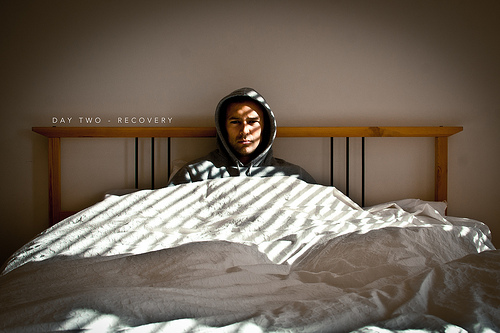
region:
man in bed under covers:
[175, 86, 317, 199]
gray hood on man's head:
[205, 84, 277, 164]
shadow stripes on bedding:
[188, 192, 303, 234]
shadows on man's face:
[237, 104, 267, 146]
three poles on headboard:
[320, 130, 375, 192]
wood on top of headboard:
[381, 119, 447, 142]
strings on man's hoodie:
[229, 159, 263, 178]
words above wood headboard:
[40, 111, 175, 129]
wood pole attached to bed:
[422, 146, 454, 211]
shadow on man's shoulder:
[195, 150, 231, 174]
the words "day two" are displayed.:
[49, 112, 102, 126]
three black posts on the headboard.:
[325, 131, 370, 207]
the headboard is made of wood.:
[33, 120, 465, 141]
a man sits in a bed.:
[212, 85, 277, 175]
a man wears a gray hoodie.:
[179, 88, 305, 188]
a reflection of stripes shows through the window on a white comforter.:
[152, 183, 337, 235]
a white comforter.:
[57, 255, 298, 320]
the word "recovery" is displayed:
[116, 115, 174, 127]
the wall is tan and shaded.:
[32, 5, 474, 87]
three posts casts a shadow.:
[118, 130, 175, 196]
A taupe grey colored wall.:
[1, 0, 496, 81]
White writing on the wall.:
[38, 112, 180, 125]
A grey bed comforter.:
[8, 265, 498, 305]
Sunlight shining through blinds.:
[116, 185, 329, 232]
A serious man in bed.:
[161, 87, 323, 183]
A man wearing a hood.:
[213, 86, 277, 168]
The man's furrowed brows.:
[223, 113, 266, 128]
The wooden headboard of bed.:
[28, 125, 215, 140]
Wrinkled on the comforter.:
[310, 260, 437, 310]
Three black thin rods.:
[323, 135, 365, 182]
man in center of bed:
[45, 65, 456, 316]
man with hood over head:
[195, 80, 310, 170]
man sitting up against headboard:
[40, 81, 451, 203]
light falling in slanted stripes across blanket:
[40, 80, 470, 305]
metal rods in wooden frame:
[30, 111, 460, 206]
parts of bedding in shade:
[46, 211, 421, 326]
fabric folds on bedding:
[165, 250, 440, 315]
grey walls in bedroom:
[100, 31, 395, 176]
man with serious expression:
[197, 72, 277, 162]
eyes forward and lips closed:
[200, 75, 295, 176]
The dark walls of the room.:
[0, 0, 499, 82]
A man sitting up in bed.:
[0, 0, 499, 332]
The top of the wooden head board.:
[276, 125, 461, 135]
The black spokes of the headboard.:
[322, 127, 379, 185]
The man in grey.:
[168, 87, 315, 184]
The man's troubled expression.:
[226, 107, 261, 152]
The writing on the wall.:
[48, 113, 178, 126]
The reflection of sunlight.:
[93, 189, 373, 244]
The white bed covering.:
[6, 238, 496, 331]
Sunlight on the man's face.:
[249, 87, 275, 158]